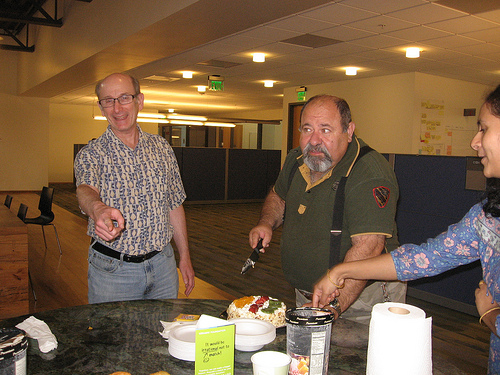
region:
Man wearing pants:
[83, 238, 186, 307]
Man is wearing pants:
[82, 242, 191, 302]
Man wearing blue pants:
[82, 245, 184, 306]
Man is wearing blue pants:
[83, 244, 183, 309]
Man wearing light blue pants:
[82, 243, 184, 307]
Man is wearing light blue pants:
[83, 235, 183, 307]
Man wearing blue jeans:
[84, 241, 184, 303]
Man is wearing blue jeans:
[84, 240, 185, 306]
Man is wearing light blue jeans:
[86, 239, 183, 308]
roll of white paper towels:
[355, 299, 447, 374]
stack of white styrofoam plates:
[215, 312, 280, 355]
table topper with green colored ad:
[182, 310, 244, 374]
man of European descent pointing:
[55, 59, 204, 307]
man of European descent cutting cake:
[234, 74, 429, 334]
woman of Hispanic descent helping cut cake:
[297, 64, 496, 367]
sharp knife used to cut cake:
[225, 229, 283, 282]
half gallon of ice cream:
[273, 300, 341, 371]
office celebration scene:
[46, 53, 478, 365]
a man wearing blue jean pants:
[73, 72, 195, 304]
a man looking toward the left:
[237, 93, 405, 321]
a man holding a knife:
[238, 90, 398, 322]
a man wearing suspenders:
[240, 90, 405, 330]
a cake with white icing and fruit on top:
[226, 292, 287, 331]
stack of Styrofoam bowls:
[222, 315, 277, 353]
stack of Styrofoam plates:
[166, 322, 206, 361]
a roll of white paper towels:
[361, 302, 434, 374]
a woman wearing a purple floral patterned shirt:
[312, 84, 499, 374]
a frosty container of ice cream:
[283, 308, 334, 373]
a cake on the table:
[212, 272, 302, 339]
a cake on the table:
[217, 282, 307, 342]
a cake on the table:
[190, 262, 287, 339]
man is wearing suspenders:
[284, 159, 369, 291]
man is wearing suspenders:
[242, 147, 360, 316]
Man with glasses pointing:
[68, 68, 200, 303]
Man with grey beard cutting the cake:
[237, 92, 412, 324]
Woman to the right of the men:
[308, 78, 498, 373]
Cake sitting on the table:
[223, 291, 292, 332]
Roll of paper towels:
[360, 298, 435, 374]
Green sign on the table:
[189, 322, 239, 374]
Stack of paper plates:
[163, 318, 216, 365]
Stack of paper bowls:
[225, 315, 277, 352]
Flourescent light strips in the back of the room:
[85, 106, 250, 133]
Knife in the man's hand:
[235, 236, 272, 274]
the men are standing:
[53, 49, 463, 364]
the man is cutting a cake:
[242, 79, 352, 244]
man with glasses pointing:
[61, 62, 202, 312]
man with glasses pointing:
[55, 60, 207, 305]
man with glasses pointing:
[55, 62, 208, 314]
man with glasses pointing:
[54, 60, 204, 315]